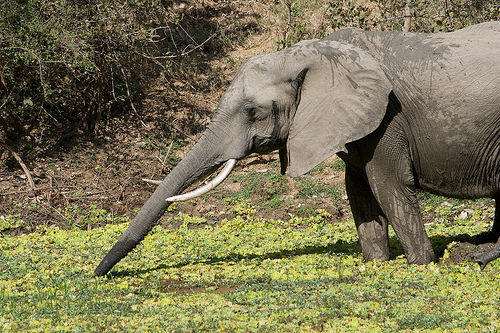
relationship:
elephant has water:
[80, 9, 499, 279] [4, 228, 496, 329]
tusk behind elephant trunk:
[139, 175, 165, 187] [95, 85, 249, 283]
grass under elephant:
[1, 199, 498, 331] [80, 9, 499, 279]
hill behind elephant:
[8, 10, 498, 211] [238, 59, 498, 162]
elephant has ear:
[80, 9, 499, 279] [282, 44, 412, 180]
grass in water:
[1, 199, 500, 333] [17, 230, 498, 315]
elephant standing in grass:
[80, 9, 499, 279] [9, 210, 480, 322]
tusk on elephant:
[166, 160, 236, 204] [99, 40, 484, 269]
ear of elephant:
[282, 44, 412, 174] [221, 21, 496, 263]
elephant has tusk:
[80, 9, 499, 279] [166, 160, 236, 204]